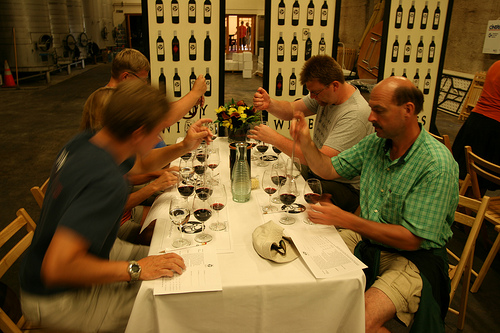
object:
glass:
[166, 193, 198, 249]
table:
[120, 130, 371, 333]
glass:
[259, 166, 281, 216]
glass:
[302, 177, 325, 226]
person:
[289, 70, 464, 332]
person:
[243, 50, 382, 216]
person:
[100, 43, 208, 156]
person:
[17, 73, 192, 333]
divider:
[141, 0, 231, 153]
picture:
[154, 26, 168, 64]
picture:
[171, 26, 183, 63]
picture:
[186, 28, 200, 63]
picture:
[203, 28, 214, 63]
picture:
[152, 0, 167, 26]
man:
[289, 70, 464, 332]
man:
[243, 50, 382, 216]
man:
[100, 43, 208, 156]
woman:
[72, 83, 183, 249]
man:
[17, 73, 192, 333]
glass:
[189, 190, 217, 247]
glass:
[275, 176, 300, 226]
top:
[20, 138, 119, 298]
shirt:
[330, 124, 458, 259]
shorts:
[331, 220, 427, 328]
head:
[370, 74, 425, 131]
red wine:
[303, 191, 322, 204]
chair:
[450, 180, 484, 330]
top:
[473, 52, 499, 128]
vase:
[224, 135, 260, 206]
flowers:
[214, 100, 260, 142]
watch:
[127, 255, 141, 285]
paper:
[280, 220, 371, 288]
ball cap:
[251, 218, 305, 265]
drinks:
[171, 141, 326, 252]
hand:
[173, 66, 209, 124]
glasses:
[260, 158, 308, 214]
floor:
[0, 38, 130, 221]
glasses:
[299, 84, 327, 95]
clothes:
[330, 131, 467, 332]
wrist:
[121, 258, 155, 285]